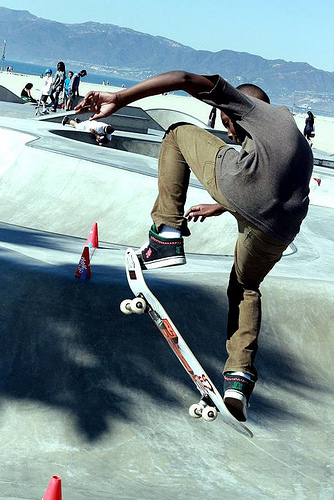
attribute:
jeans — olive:
[131, 121, 297, 351]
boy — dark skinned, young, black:
[77, 66, 314, 420]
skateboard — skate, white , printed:
[124, 245, 253, 438]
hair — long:
[307, 109, 314, 125]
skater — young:
[35, 66, 56, 106]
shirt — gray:
[190, 70, 315, 245]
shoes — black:
[138, 229, 258, 421]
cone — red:
[40, 473, 63, 498]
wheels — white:
[119, 296, 146, 315]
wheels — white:
[186, 401, 218, 421]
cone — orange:
[74, 249, 95, 279]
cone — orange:
[84, 221, 98, 247]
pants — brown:
[148, 119, 284, 375]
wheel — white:
[128, 296, 147, 314]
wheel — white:
[117, 298, 133, 314]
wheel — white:
[201, 402, 222, 420]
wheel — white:
[188, 402, 201, 415]